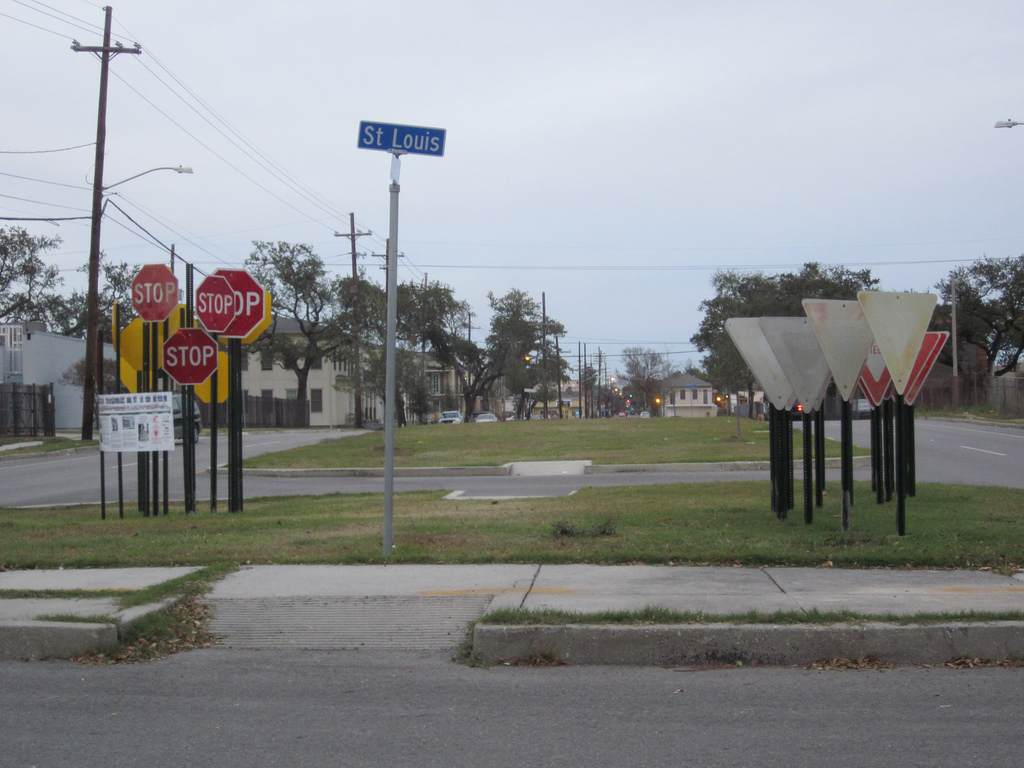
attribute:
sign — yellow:
[192, 275, 235, 336]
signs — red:
[125, 265, 304, 395]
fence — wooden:
[233, 385, 316, 427]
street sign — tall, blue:
[347, 116, 440, 562]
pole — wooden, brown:
[328, 147, 445, 582]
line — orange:
[414, 577, 591, 600]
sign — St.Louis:
[356, 114, 449, 160]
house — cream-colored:
[657, 370, 719, 418]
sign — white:
[378, 161, 409, 298]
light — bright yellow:
[709, 389, 727, 405]